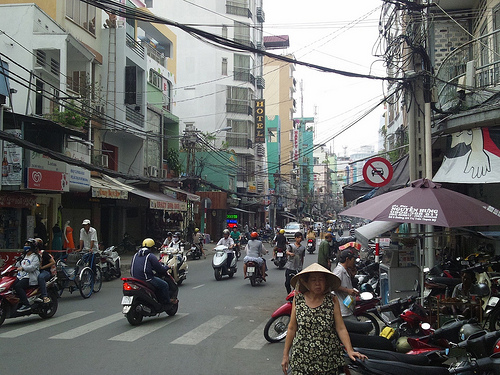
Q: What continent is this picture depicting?
A: Asia.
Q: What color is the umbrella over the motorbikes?
A: Purple.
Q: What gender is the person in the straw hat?
A: Female.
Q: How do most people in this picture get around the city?
A: Motorcycle.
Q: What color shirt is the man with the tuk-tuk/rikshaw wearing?
A: White.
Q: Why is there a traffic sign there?
A: To say no cars are allowed.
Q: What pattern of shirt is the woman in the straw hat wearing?
A: Floral.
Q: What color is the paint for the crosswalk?
A: White.